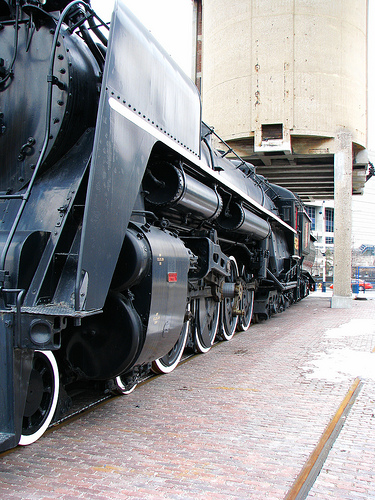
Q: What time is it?
A: Afternoon.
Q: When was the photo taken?
A: During the daytime.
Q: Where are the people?
A: None in photo.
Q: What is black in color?
A: Train.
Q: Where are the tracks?
A: Under the train.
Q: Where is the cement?
A: Next to train.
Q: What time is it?
A: Afternoon.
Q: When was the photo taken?
A: In daytime.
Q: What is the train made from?
A: Metal.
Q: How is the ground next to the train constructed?
A: From brick.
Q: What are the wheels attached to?
A: A train.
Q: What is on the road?
A: A train.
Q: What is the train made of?
A: Metal.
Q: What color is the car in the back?
A: Red.